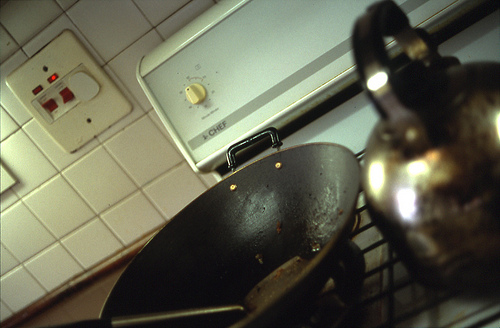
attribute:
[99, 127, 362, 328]
pan — empty, black, round, dirty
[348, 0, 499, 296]
kettle — metal, shiny, black, silver, tarnished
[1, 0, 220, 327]
tiles — square, white, backsplash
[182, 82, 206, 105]
knob — small, white, yellow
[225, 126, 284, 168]
handle — black, shiny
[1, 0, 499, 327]
kitchen — scene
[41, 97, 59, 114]
switch — red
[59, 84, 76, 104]
switch — red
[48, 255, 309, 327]
spatula — metal, used, stainless steel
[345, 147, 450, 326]
burner grates — black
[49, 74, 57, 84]
light — tiny, shining, red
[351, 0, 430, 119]
handle — shiny, curved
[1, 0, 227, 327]
wall — tiled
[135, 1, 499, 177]
back panel — white